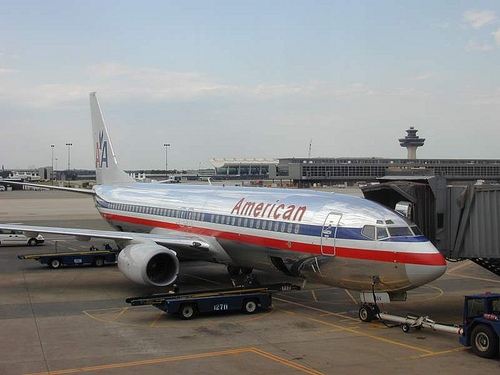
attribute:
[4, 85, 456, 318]
plane — large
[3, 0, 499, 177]
sky — blue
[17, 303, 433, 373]
lines — yellow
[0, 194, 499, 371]
airport — large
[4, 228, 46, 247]
car — white